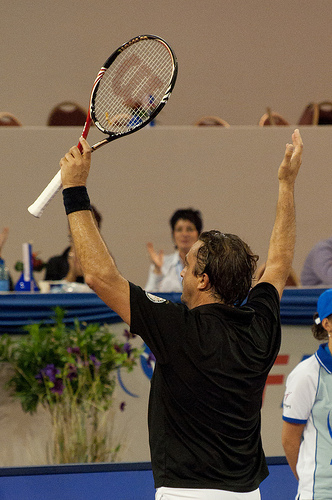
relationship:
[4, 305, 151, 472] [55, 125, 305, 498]
plant in front of man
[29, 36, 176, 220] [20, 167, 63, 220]
racket with grip